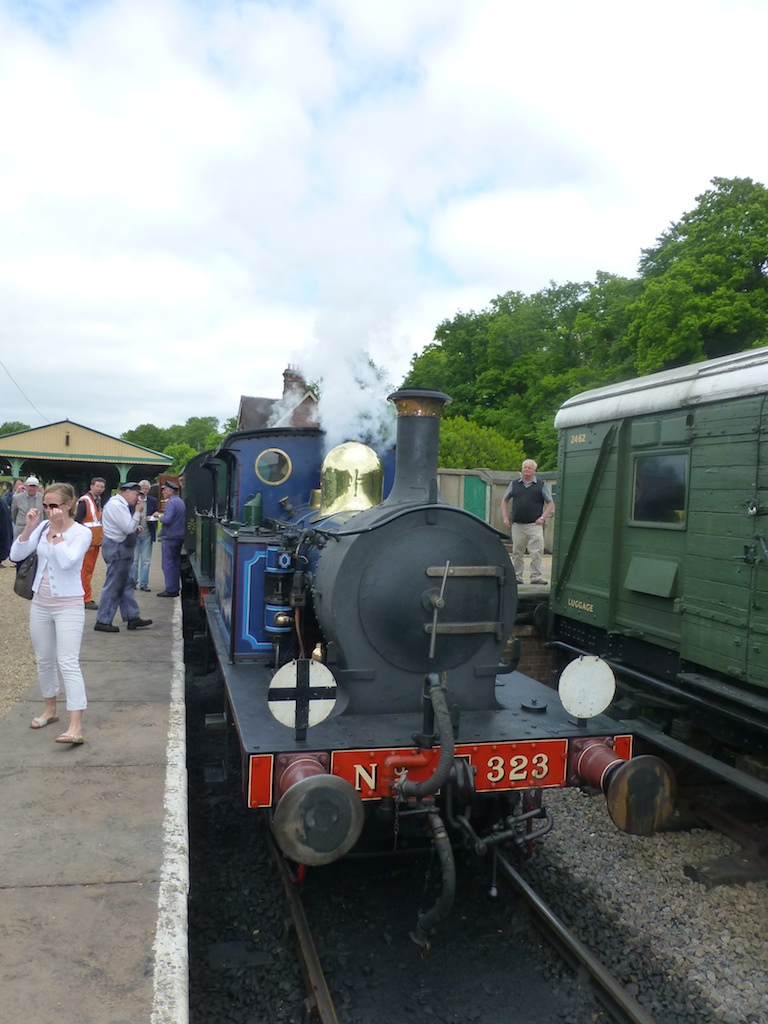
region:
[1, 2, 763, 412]
the sky is blue and has white clouds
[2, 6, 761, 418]
white clouds are covering the blue sky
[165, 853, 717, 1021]
this portion of gravels are wet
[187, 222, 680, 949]
the smoke is coming out of the engine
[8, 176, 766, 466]
trees with green leaves in their branches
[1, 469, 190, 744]
people are walking in the platform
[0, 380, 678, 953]
the train engine is standing beside the platform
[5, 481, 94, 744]
the woman is wearing a white dress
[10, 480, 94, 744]
the woman is wearing a wrist watch around her wrist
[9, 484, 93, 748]
woman adjusting her glasses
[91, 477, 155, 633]
conductor wearing hat and overalls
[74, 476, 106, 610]
man wearing orange vest and pants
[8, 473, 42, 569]
old man wearing white hat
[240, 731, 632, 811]
red paint with white numbers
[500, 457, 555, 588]
man wearing khaki pants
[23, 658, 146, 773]
the foot of a woman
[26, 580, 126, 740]
a woman wearing pants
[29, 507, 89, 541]
the hand of a woman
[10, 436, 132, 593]
the arm of a woman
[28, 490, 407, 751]
a woman near a train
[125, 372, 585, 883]
a train on train tracks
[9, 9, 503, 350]
clouds in the sky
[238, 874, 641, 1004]
the train tracks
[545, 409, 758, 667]
a green train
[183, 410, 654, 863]
a blue train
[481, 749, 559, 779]
the number on the train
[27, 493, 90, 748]
a lady in a white shirt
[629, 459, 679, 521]
a window on the train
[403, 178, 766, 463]
a tree behind the train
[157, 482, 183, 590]
a man in a blue shirt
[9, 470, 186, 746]
people standing by the train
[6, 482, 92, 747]
person waiting on the train platform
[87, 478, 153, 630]
person waiting on the train platform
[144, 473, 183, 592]
person waiting on the train platform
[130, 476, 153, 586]
person waiting on the train platform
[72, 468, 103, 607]
person waiting on the train platform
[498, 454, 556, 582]
person waiting on the train platform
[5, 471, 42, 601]
person waiting on the train platform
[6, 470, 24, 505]
person waiting on the train platform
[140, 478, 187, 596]
person waiting on the train platform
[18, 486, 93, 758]
A person is standing up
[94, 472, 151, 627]
A person is standing up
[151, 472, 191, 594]
A person is standing up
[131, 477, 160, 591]
A person is standing up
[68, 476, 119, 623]
A person is standing up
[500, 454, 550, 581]
A person is standing up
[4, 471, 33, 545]
A person is standing up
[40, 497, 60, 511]
dark black sunglasses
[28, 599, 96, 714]
a woman's white capri pants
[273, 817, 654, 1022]
a small train track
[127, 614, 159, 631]
a man's black shoe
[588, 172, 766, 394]
a large green tree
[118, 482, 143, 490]
a man's blue hat